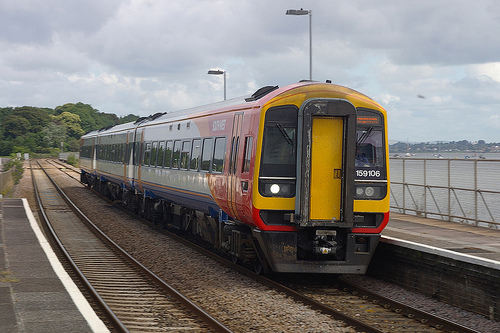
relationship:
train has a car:
[80, 78, 392, 275] [132, 78, 391, 281]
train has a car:
[80, 78, 392, 275] [92, 113, 138, 214]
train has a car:
[80, 78, 392, 275] [78, 126, 97, 195]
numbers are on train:
[355, 169, 382, 177] [80, 78, 392, 275]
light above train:
[283, 7, 308, 17] [80, 78, 392, 275]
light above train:
[205, 68, 225, 76] [80, 78, 392, 275]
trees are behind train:
[0, 101, 166, 157] [80, 78, 392, 275]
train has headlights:
[80, 78, 392, 275] [269, 185, 375, 198]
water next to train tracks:
[386, 151, 498, 229] [28, 155, 477, 331]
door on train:
[308, 116, 343, 223] [80, 78, 392, 275]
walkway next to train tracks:
[381, 206, 498, 266] [28, 155, 477, 331]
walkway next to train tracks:
[2, 196, 113, 331] [28, 155, 477, 331]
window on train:
[143, 120, 385, 174] [80, 78, 392, 275]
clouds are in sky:
[1, 2, 498, 144] [1, 1, 499, 145]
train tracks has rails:
[28, 155, 477, 331] [26, 155, 477, 333]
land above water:
[388, 142, 497, 152] [386, 151, 498, 229]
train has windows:
[80, 78, 392, 275] [142, 133, 254, 175]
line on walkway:
[378, 233, 499, 267] [381, 206, 498, 266]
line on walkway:
[19, 197, 109, 332] [2, 196, 113, 331]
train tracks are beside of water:
[28, 155, 477, 331] [386, 151, 498, 229]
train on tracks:
[80, 78, 392, 275] [45, 153, 486, 331]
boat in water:
[476, 153, 484, 160] [386, 151, 498, 229]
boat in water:
[460, 155, 472, 161] [386, 151, 498, 229]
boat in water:
[428, 153, 445, 160] [386, 151, 498, 229]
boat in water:
[401, 151, 417, 158] [386, 151, 498, 229]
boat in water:
[391, 151, 401, 160] [386, 151, 498, 229]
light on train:
[267, 182, 281, 196] [80, 78, 392, 275]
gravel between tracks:
[37, 157, 359, 332] [45, 153, 486, 331]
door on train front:
[308, 116, 343, 223] [252, 81, 392, 280]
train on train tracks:
[80, 78, 392, 275] [28, 155, 477, 331]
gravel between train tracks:
[37, 157, 359, 332] [28, 155, 477, 331]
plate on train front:
[253, 231, 382, 275] [252, 81, 392, 280]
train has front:
[80, 78, 392, 275] [252, 81, 392, 280]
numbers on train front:
[355, 169, 382, 177] [252, 81, 392, 280]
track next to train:
[28, 156, 234, 331] [80, 78, 392, 275]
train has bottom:
[80, 78, 392, 275] [75, 169, 255, 261]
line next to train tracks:
[378, 233, 499, 267] [28, 155, 477, 331]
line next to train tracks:
[19, 197, 109, 332] [28, 155, 477, 331]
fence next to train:
[391, 158, 498, 230] [80, 78, 392, 275]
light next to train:
[283, 7, 308, 17] [80, 78, 392, 275]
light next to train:
[205, 68, 225, 76] [80, 78, 392, 275]